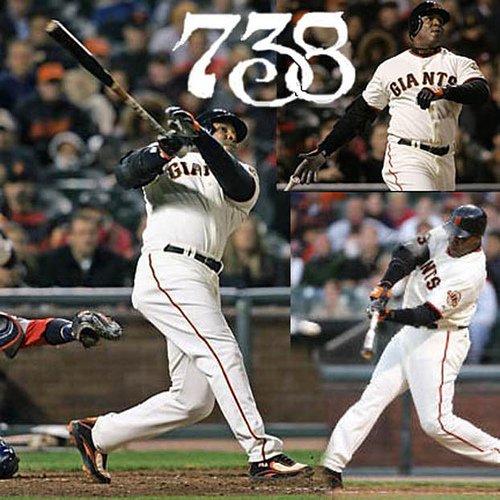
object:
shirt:
[135, 152, 259, 262]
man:
[67, 106, 314, 483]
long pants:
[90, 243, 283, 462]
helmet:
[409, 2, 451, 37]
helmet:
[197, 109, 247, 144]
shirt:
[362, 48, 487, 148]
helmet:
[441, 204, 487, 238]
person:
[315, 204, 500, 492]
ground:
[0, 438, 500, 500]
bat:
[361, 310, 380, 359]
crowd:
[0, 0, 499, 319]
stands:
[0, 306, 499, 467]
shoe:
[248, 454, 314, 481]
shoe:
[315, 467, 343, 489]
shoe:
[66, 416, 110, 484]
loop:
[184, 244, 197, 259]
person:
[0, 313, 73, 477]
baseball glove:
[73, 310, 123, 349]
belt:
[398, 138, 449, 157]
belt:
[414, 321, 470, 330]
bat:
[45, 20, 188, 158]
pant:
[67, 245, 314, 487]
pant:
[317, 324, 500, 473]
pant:
[381, 134, 455, 191]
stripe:
[386, 144, 402, 193]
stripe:
[147, 251, 266, 461]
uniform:
[92, 152, 284, 464]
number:
[173, 11, 357, 107]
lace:
[275, 454, 293, 464]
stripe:
[437, 331, 500, 453]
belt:
[164, 245, 222, 273]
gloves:
[157, 106, 204, 159]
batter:
[67, 107, 316, 481]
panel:
[370, 285, 391, 299]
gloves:
[366, 283, 392, 318]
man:
[292, 0, 489, 191]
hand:
[73, 317, 109, 345]